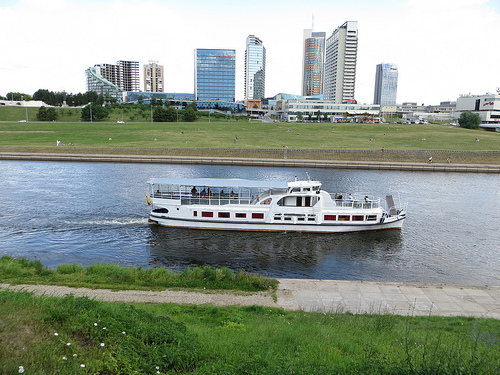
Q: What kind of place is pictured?
A: It is a river.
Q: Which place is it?
A: It is a river.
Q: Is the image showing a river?
A: Yes, it is showing a river.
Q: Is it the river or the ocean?
A: It is the river.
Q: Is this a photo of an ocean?
A: No, the picture is showing a river.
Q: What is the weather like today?
A: It is cloudy.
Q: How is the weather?
A: It is cloudy.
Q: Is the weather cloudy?
A: Yes, it is cloudy.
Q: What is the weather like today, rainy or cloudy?
A: It is cloudy.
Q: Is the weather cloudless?
A: No, it is cloudy.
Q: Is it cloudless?
A: No, it is cloudy.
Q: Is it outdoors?
A: Yes, it is outdoors.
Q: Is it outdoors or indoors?
A: It is outdoors.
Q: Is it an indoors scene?
A: No, it is outdoors.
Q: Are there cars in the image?
A: No, there are no cars.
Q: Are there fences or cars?
A: No, there are no cars or fences.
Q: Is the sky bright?
A: Yes, the sky is bright.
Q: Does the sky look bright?
A: Yes, the sky is bright.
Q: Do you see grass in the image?
A: Yes, there is grass.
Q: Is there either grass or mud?
A: Yes, there is grass.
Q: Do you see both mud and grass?
A: No, there is grass but no mud.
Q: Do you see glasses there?
A: No, there are no glasses.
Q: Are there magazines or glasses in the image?
A: No, there are no glasses or magazines.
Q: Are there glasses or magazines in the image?
A: No, there are no glasses or magazines.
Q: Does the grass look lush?
A: Yes, the grass is lush.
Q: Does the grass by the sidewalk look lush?
A: Yes, the grass is lush.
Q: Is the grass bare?
A: No, the grass is lush.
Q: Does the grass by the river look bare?
A: No, the grass is lush.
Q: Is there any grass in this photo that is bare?
A: No, there is grass but it is lush.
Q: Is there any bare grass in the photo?
A: No, there is grass but it is lush.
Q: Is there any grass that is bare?
A: No, there is grass but it is lush.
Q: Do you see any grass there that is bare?
A: No, there is grass but it is lush.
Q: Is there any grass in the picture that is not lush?
A: No, there is grass but it is lush.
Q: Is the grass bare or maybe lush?
A: The grass is lush.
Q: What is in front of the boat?
A: The grass is in front of the boat.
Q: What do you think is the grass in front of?
A: The grass is in front of the boat.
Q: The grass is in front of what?
A: The grass is in front of the boat.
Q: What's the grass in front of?
A: The grass is in front of the boat.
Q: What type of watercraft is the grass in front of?
A: The grass is in front of the boat.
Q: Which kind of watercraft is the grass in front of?
A: The grass is in front of the boat.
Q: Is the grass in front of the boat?
A: Yes, the grass is in front of the boat.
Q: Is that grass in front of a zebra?
A: No, the grass is in front of the boat.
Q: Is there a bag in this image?
A: No, there are no bags.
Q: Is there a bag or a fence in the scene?
A: No, there are no bags or fences.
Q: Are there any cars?
A: No, there are no cars.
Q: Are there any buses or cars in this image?
A: No, there are no cars or buses.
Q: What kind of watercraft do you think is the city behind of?
A: The city is behind the boat.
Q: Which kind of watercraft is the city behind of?
A: The city is behind the boat.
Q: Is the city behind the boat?
A: Yes, the city is behind the boat.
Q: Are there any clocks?
A: No, there are no clocks.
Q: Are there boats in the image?
A: Yes, there is a boat.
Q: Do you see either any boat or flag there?
A: Yes, there is a boat.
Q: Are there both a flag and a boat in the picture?
A: No, there is a boat but no flags.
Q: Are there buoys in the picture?
A: No, there are no buoys.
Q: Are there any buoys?
A: No, there are no buoys.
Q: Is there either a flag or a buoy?
A: No, there are no buoys or flags.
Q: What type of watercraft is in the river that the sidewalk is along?
A: The watercraft is a boat.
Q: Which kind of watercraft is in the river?
A: The watercraft is a boat.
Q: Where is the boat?
A: The boat is in the river.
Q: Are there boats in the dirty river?
A: Yes, there is a boat in the river.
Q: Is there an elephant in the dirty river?
A: No, there is a boat in the river.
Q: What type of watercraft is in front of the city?
A: The watercraft is a boat.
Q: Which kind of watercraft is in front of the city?
A: The watercraft is a boat.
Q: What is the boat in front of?
A: The boat is in front of the city.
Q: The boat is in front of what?
A: The boat is in front of the city.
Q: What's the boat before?
A: The boat is in front of the city.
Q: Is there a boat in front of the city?
A: Yes, there is a boat in front of the city.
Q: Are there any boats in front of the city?
A: Yes, there is a boat in front of the city.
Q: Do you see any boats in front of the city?
A: Yes, there is a boat in front of the city.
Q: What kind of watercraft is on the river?
A: The watercraft is a boat.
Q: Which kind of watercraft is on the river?
A: The watercraft is a boat.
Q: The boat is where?
A: The boat is on the river.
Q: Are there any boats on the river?
A: Yes, there is a boat on the river.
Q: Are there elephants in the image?
A: No, there are no elephants.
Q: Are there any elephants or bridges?
A: No, there are no elephants or bridges.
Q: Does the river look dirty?
A: Yes, the river is dirty.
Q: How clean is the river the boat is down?
A: The river is dirty.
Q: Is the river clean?
A: No, the river is dirty.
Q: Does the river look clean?
A: No, the river is dirty.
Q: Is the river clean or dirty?
A: The river is dirty.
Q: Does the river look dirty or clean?
A: The river is dirty.